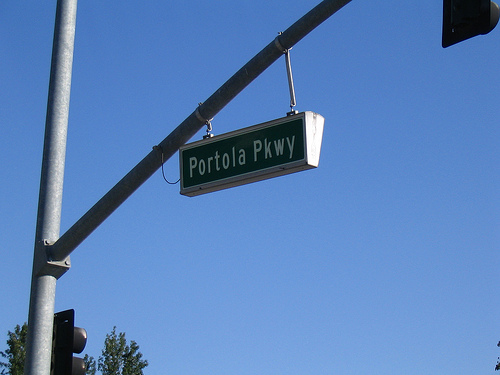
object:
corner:
[302, 112, 325, 170]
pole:
[46, 0, 349, 264]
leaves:
[108, 355, 118, 361]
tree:
[98, 324, 148, 374]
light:
[50, 307, 89, 373]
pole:
[24, 0, 80, 374]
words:
[184, 146, 245, 177]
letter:
[236, 147, 245, 170]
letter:
[250, 138, 262, 162]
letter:
[197, 158, 206, 177]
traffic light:
[439, 0, 499, 50]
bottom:
[440, 16, 499, 50]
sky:
[0, 1, 499, 374]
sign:
[178, 111, 323, 199]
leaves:
[113, 339, 125, 349]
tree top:
[98, 324, 147, 367]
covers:
[72, 326, 88, 355]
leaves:
[125, 350, 133, 355]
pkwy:
[250, 134, 297, 161]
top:
[53, 308, 76, 323]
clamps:
[270, 31, 295, 54]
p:
[186, 154, 199, 180]